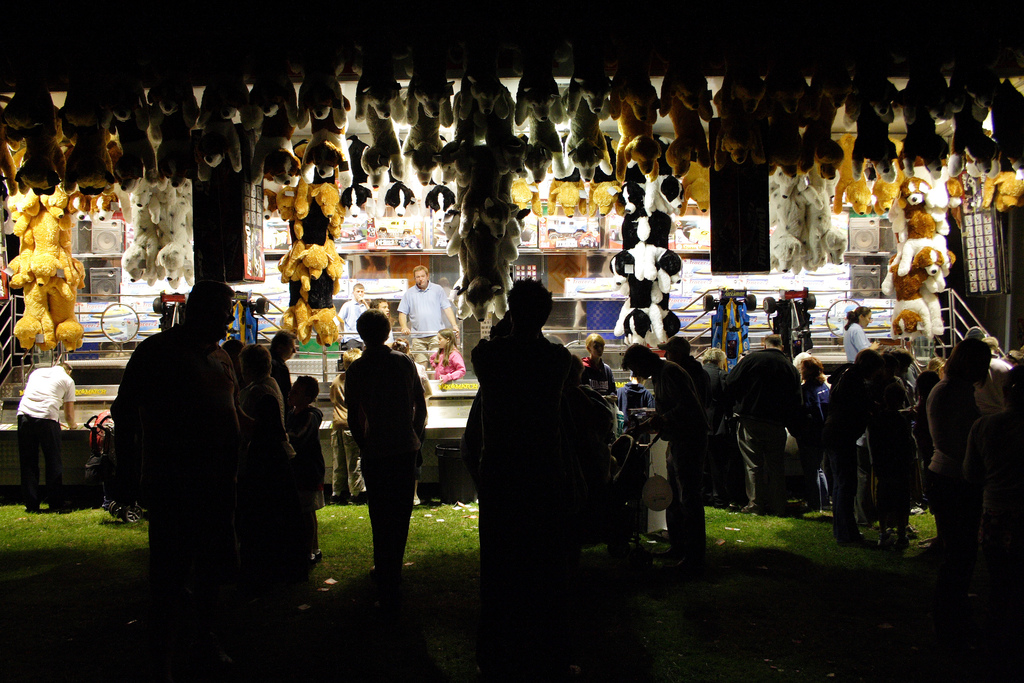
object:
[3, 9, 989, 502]
booth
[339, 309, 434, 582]
person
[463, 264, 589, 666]
person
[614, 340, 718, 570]
person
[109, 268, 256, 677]
person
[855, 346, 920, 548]
person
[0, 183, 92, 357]
animal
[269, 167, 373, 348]
animal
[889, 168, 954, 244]
stuffed animal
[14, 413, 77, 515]
pants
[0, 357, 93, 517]
man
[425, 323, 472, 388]
girl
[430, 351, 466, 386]
sweatshirt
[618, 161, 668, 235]
plush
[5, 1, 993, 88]
roof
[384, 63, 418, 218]
plushes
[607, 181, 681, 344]
animal